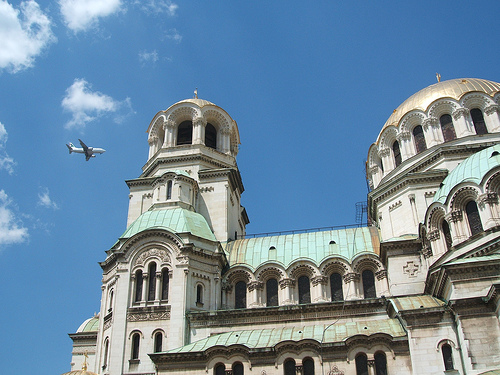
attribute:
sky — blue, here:
[59, 2, 312, 90]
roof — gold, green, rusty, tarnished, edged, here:
[241, 221, 373, 269]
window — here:
[214, 259, 305, 301]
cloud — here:
[29, 8, 92, 56]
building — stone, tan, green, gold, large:
[371, 91, 499, 305]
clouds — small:
[71, 78, 137, 115]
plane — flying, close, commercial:
[56, 131, 107, 173]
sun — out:
[115, 33, 257, 66]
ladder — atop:
[179, 144, 232, 221]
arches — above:
[160, 112, 199, 146]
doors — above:
[168, 118, 217, 179]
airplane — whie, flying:
[14, 102, 162, 195]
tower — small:
[135, 102, 277, 253]